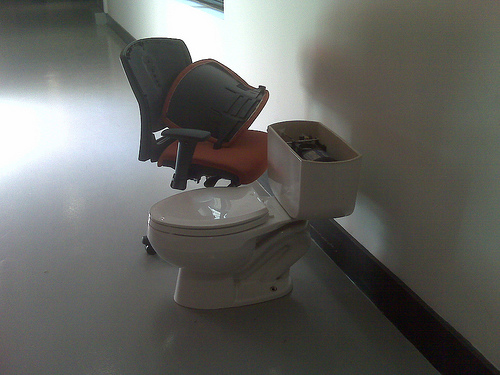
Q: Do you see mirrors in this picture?
A: No, there are no mirrors.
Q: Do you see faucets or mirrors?
A: No, there are no mirrors or faucets.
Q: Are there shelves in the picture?
A: No, there are no shelves.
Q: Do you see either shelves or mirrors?
A: No, there are no shelves or mirrors.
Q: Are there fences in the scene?
A: No, there are no fences.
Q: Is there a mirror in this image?
A: No, there are no mirrors.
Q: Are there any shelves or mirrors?
A: No, there are no mirrors or shelves.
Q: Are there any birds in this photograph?
A: Yes, there is a bird.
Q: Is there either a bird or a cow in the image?
A: Yes, there is a bird.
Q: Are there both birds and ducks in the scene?
A: No, there is a bird but no ducks.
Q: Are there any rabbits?
A: No, there are no rabbits.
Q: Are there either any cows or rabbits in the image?
A: No, there are no rabbits or cows.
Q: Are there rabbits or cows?
A: No, there are no rabbits or cows.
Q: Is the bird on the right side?
A: Yes, the bird is on the right of the image.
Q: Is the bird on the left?
A: No, the bird is on the right of the image.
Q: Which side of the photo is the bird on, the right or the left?
A: The bird is on the right of the image.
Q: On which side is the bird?
A: The bird is on the right of the image.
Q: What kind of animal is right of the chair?
A: The animal is a bird.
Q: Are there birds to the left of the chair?
A: No, the bird is to the right of the chair.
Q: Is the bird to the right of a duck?
A: No, the bird is to the right of the chair.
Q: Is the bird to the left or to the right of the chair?
A: The bird is to the right of the chair.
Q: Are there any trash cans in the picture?
A: No, there are no trash cans.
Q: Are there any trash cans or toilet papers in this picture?
A: No, there are no trash cans or toilet papers.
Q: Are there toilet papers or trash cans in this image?
A: No, there are no trash cans or toilet papers.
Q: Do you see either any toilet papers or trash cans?
A: No, there are no trash cans or toilet papers.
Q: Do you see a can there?
A: No, there are no cans.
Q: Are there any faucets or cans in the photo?
A: No, there are no cans or faucets.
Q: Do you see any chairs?
A: Yes, there is a chair.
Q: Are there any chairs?
A: Yes, there is a chair.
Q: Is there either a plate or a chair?
A: Yes, there is a chair.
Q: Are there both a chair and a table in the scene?
A: No, there is a chair but no tables.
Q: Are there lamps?
A: No, there are no lamps.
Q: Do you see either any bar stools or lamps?
A: No, there are no lamps or bar stools.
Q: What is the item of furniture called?
A: The piece of furniture is a chair.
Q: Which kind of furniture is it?
A: The piece of furniture is a chair.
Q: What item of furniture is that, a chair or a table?
A: This is a chair.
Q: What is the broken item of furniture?
A: The piece of furniture is a chair.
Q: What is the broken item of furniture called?
A: The piece of furniture is a chair.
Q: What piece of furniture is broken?
A: The piece of furniture is a chair.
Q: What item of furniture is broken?
A: The piece of furniture is a chair.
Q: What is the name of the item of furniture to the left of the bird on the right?
A: The piece of furniture is a chair.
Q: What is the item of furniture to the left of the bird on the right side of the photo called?
A: The piece of furniture is a chair.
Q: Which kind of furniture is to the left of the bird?
A: The piece of furniture is a chair.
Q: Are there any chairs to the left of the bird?
A: Yes, there is a chair to the left of the bird.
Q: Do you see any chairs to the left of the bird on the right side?
A: Yes, there is a chair to the left of the bird.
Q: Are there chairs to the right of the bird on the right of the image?
A: No, the chair is to the left of the bird.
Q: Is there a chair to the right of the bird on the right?
A: No, the chair is to the left of the bird.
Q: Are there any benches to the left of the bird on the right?
A: No, there is a chair to the left of the bird.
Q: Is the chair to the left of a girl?
A: No, the chair is to the left of a bird.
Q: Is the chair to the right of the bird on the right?
A: No, the chair is to the left of the bird.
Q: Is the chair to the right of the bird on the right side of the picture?
A: No, the chair is to the left of the bird.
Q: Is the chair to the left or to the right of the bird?
A: The chair is to the left of the bird.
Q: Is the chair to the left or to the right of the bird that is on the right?
A: The chair is to the left of the bird.